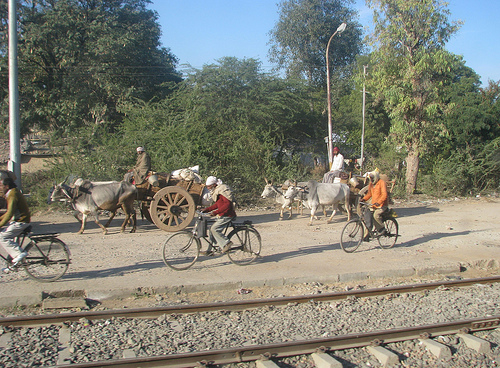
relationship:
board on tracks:
[456, 333, 491, 359] [1, 270, 498, 366]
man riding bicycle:
[0, 168, 36, 263] [0, 217, 73, 280]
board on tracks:
[415, 335, 460, 357] [1, 270, 498, 366]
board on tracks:
[59, 326, 71, 366] [1, 270, 498, 366]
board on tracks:
[57, 326, 75, 366] [122, 320, 499, 367]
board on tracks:
[166, 315, 190, 353] [1, 270, 498, 366]